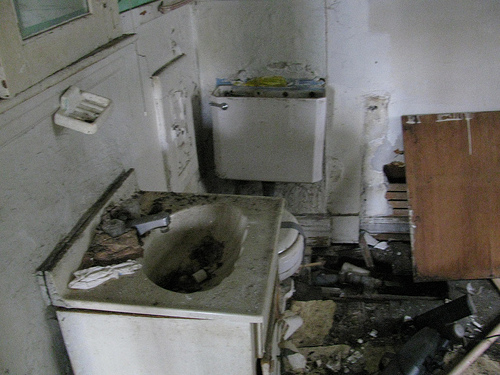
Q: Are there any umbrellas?
A: No, there are no umbrellas.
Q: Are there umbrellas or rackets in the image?
A: No, there are no umbrellas or rackets.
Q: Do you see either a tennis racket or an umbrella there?
A: No, there are no umbrellas or rackets.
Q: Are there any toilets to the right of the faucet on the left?
A: Yes, there is a toilet to the right of the tap.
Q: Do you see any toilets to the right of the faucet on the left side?
A: Yes, there is a toilet to the right of the tap.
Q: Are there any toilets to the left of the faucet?
A: No, the toilet is to the right of the faucet.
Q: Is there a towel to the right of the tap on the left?
A: No, there is a toilet to the right of the tap.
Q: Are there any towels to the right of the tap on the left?
A: No, there is a toilet to the right of the tap.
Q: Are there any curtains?
A: No, there are no curtains.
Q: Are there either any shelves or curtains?
A: No, there are no curtains or shelves.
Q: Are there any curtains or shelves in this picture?
A: No, there are no curtains or shelves.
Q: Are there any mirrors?
A: No, there are no mirrors.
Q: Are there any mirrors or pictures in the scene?
A: No, there are no mirrors or pictures.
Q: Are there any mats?
A: No, there are no mats.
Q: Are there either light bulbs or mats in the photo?
A: No, there are no mats or light bulbs.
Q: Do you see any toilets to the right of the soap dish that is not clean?
A: Yes, there is a toilet to the right of the soap dish.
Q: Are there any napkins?
A: No, there are no napkins.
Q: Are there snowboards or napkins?
A: No, there are no napkins or snowboards.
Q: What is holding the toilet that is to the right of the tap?
A: The tape is holding the toilet.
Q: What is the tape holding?
A: The tape is holding the toilet.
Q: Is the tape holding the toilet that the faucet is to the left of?
A: Yes, the tape is holding the toilet.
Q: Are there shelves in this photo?
A: No, there are no shelves.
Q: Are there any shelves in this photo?
A: No, there are no shelves.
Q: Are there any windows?
A: Yes, there is a window.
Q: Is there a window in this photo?
A: Yes, there is a window.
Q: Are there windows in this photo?
A: Yes, there is a window.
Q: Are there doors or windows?
A: Yes, there is a window.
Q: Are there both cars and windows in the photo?
A: No, there is a window but no cars.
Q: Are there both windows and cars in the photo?
A: No, there is a window but no cars.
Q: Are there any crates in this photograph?
A: No, there are no crates.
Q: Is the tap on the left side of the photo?
A: Yes, the tap is on the left of the image.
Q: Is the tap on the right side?
A: No, the tap is on the left of the image.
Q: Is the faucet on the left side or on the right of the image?
A: The faucet is on the left of the image.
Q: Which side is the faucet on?
A: The faucet is on the left of the image.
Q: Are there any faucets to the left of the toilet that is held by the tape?
A: Yes, there is a faucet to the left of the toilet.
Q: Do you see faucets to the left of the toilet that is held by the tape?
A: Yes, there is a faucet to the left of the toilet.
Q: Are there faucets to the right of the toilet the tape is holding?
A: No, the faucet is to the left of the toilet.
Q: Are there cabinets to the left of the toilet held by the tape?
A: No, there is a faucet to the left of the toilet.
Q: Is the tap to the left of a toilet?
A: Yes, the tap is to the left of a toilet.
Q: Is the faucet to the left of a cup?
A: No, the faucet is to the left of a toilet.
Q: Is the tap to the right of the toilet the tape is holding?
A: No, the tap is to the left of the toilet.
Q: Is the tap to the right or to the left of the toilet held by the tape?
A: The tap is to the left of the toilet.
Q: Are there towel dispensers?
A: No, there are no towel dispensers.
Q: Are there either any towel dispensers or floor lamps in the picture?
A: No, there are no towel dispensers or floor lamps.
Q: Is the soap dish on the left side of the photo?
A: Yes, the soap dish is on the left of the image.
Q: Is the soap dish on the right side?
A: No, the soap dish is on the left of the image.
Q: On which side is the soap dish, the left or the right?
A: The soap dish is on the left of the image.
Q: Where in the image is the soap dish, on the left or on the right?
A: The soap dish is on the left of the image.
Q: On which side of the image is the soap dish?
A: The soap dish is on the left of the image.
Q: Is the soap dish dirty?
A: Yes, the soap dish is dirty.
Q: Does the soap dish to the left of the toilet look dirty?
A: Yes, the soap dish is dirty.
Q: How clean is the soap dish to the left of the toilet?
A: The soap dish is dirty.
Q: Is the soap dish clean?
A: No, the soap dish is dirty.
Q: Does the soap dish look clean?
A: No, the soap dish is dirty.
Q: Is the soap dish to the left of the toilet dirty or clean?
A: The soap dish is dirty.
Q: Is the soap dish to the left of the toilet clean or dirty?
A: The soap dish is dirty.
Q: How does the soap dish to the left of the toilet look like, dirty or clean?
A: The soap dish is dirty.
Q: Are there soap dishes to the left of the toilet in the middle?
A: Yes, there is a soap dish to the left of the toilet.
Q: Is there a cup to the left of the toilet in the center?
A: No, there is a soap dish to the left of the toilet.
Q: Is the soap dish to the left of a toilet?
A: Yes, the soap dish is to the left of a toilet.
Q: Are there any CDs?
A: No, there are no cds.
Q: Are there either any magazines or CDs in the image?
A: No, there are no CDs or magazines.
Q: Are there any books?
A: No, there are no books.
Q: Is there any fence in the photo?
A: No, there are no fences.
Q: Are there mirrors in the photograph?
A: No, there are no mirrors.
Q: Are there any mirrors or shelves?
A: No, there are no mirrors or shelves.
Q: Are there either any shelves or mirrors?
A: No, there are no mirrors or shelves.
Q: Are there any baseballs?
A: No, there are no baseballs.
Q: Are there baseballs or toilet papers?
A: No, there are no baseballs or toilet papers.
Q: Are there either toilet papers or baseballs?
A: No, there are no baseballs or toilet papers.